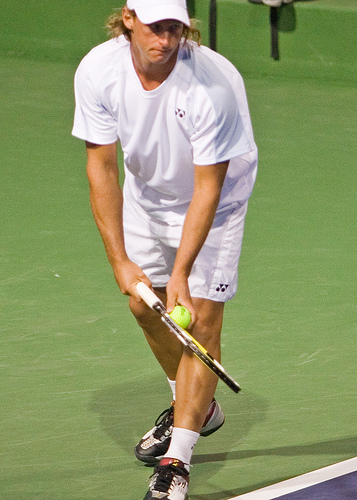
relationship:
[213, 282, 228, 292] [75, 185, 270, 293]
brand logo on shorts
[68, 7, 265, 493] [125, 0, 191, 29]
man wearing a cap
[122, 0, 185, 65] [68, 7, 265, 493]
head of man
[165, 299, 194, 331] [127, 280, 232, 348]
ball on racket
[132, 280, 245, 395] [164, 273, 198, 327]
racket in hand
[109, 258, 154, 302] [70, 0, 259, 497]
hand on man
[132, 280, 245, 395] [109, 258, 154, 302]
racket in hand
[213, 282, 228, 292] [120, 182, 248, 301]
brand logo on shorts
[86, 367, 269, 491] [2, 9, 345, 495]
shadow on tennis court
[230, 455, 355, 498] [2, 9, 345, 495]
boundary line on tennis court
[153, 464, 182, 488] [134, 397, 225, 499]
shoe lace on shoes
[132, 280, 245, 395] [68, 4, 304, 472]
racket of tennis player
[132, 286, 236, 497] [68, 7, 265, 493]
legs of man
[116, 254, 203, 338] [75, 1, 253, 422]
hands of man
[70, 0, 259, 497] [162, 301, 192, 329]
man to serve ball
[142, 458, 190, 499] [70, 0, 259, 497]
sneaker on man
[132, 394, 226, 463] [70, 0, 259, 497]
sneaker on man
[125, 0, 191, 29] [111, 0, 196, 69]
cap on head